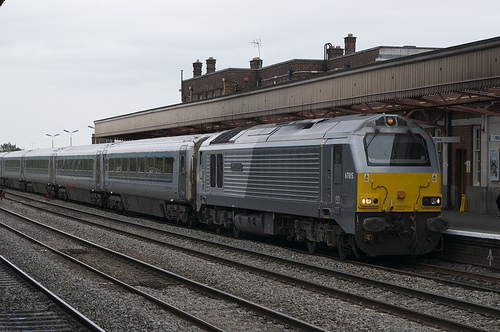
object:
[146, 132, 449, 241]
train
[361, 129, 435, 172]
window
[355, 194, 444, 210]
lights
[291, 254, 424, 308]
track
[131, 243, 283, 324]
tracks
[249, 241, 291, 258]
rocks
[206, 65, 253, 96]
roof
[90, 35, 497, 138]
building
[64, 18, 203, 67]
sky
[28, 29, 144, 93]
clouds